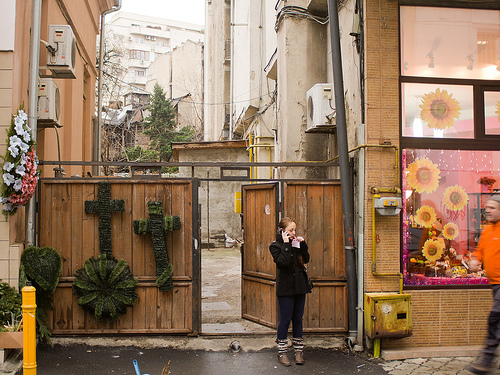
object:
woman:
[269, 217, 314, 366]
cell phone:
[279, 227, 290, 238]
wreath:
[74, 257, 137, 319]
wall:
[34, 178, 196, 336]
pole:
[20, 285, 40, 373]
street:
[0, 348, 499, 374]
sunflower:
[415, 88, 462, 134]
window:
[398, 4, 498, 291]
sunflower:
[405, 158, 441, 195]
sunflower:
[441, 185, 470, 212]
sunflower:
[414, 204, 436, 227]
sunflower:
[441, 223, 459, 240]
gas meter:
[362, 291, 414, 340]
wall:
[0, 0, 124, 290]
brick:
[394, 360, 419, 373]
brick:
[420, 357, 447, 369]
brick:
[434, 364, 461, 374]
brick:
[411, 366, 438, 374]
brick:
[445, 358, 469, 369]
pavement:
[0, 346, 500, 374]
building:
[169, 1, 500, 362]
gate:
[240, 183, 280, 331]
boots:
[275, 339, 291, 366]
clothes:
[269, 235, 314, 342]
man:
[465, 195, 499, 374]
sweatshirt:
[473, 222, 499, 283]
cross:
[83, 181, 126, 256]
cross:
[135, 198, 179, 293]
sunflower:
[421, 239, 444, 262]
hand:
[280, 231, 291, 239]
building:
[2, 0, 121, 293]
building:
[144, 38, 207, 178]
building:
[94, 10, 209, 177]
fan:
[305, 81, 341, 134]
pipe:
[325, 0, 357, 347]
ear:
[277, 228, 283, 236]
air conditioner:
[48, 23, 78, 79]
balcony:
[129, 26, 172, 42]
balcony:
[124, 78, 147, 87]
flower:
[13, 123, 24, 136]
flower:
[18, 109, 29, 121]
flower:
[0, 162, 15, 174]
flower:
[14, 179, 24, 191]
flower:
[3, 170, 17, 186]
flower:
[10, 135, 22, 145]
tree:
[124, 82, 201, 175]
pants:
[276, 293, 307, 338]